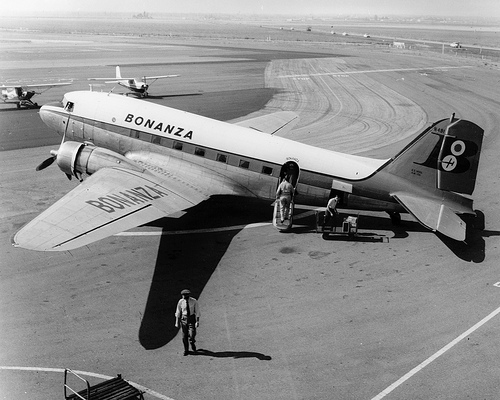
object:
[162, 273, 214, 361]
person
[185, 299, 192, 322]
tie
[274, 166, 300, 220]
person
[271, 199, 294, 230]
stairs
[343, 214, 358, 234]
package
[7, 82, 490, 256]
plane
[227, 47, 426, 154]
runway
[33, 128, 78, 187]
propeller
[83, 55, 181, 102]
airplane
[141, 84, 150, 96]
propeller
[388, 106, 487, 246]
tail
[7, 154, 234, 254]
wing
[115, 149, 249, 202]
left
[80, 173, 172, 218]
bonanza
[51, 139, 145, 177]
engine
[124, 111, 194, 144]
bonanza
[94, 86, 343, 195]
fuselage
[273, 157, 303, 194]
door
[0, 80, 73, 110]
planes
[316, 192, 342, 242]
man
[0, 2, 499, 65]
field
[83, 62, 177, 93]
planes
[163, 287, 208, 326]
pilot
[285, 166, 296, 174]
inside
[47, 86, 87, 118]
cockpit